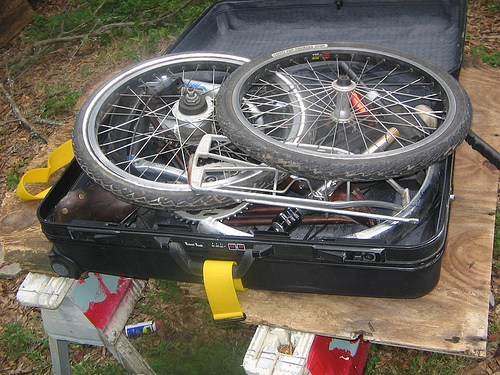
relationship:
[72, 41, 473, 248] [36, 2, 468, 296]
bike inside suitcase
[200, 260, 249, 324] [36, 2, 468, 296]
strap on suitcase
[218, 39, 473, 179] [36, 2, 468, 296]
tire on top suitcase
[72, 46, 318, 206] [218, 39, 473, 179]
tire below tire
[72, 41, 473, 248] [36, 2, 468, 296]
bike parts in suitcase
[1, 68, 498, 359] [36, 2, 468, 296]
wood under suitcase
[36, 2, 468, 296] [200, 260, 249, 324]
suitcase has strap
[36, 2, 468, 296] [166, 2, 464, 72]
suitcase has lid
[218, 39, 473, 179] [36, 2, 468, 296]
tire in suitcase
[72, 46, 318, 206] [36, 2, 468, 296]
tire in suitcase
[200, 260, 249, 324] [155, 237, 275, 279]
strap on handle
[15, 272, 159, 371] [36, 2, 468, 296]
saw horse under suitcase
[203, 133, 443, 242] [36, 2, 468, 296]
bike rack in suitcase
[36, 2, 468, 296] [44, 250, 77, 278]
suitcase has wheel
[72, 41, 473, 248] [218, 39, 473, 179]
bike has tire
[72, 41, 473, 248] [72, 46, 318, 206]
bike has tire